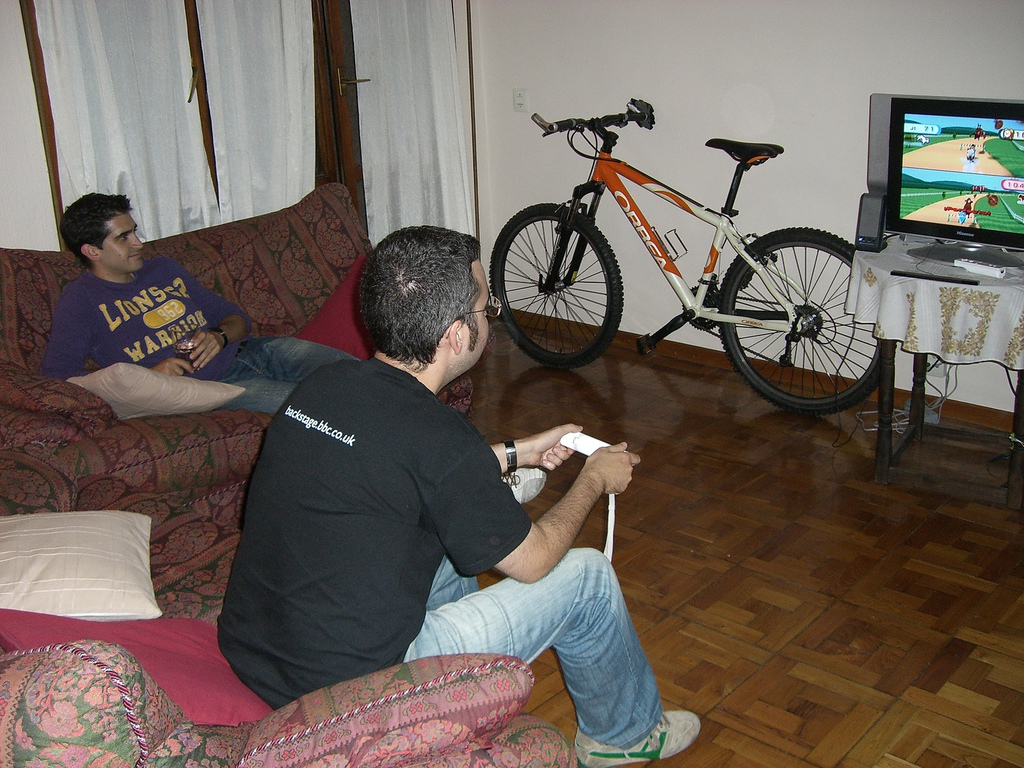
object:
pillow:
[0, 610, 277, 728]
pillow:
[0, 508, 164, 627]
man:
[41, 193, 362, 414]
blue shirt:
[43, 255, 253, 385]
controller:
[559, 431, 630, 565]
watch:
[501, 440, 518, 472]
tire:
[488, 203, 625, 370]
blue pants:
[400, 546, 665, 752]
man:
[216, 224, 704, 768]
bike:
[487, 98, 897, 417]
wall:
[465, 0, 1024, 418]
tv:
[865, 93, 1024, 253]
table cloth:
[844, 236, 1024, 372]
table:
[843, 242, 1024, 494]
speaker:
[855, 193, 890, 253]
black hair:
[356, 224, 480, 371]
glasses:
[466, 297, 502, 319]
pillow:
[65, 362, 246, 422]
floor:
[458, 304, 1024, 768]